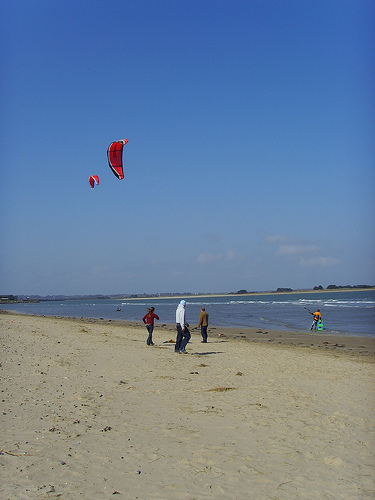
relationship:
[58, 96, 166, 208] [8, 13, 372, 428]
kite in sky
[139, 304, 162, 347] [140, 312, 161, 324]
boy wearing shirt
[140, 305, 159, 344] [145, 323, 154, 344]
boy wearing jeans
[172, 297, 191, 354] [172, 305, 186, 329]
man wearing shirt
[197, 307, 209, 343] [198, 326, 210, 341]
man wearing jeans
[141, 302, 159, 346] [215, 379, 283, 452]
boy on beach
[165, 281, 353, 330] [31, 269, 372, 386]
waves in water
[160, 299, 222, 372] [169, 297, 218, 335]
person wearing hoodie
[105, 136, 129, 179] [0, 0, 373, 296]
kite in sky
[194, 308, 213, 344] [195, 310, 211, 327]
man wearing jacket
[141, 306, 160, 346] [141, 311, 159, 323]
girl wearing shirt